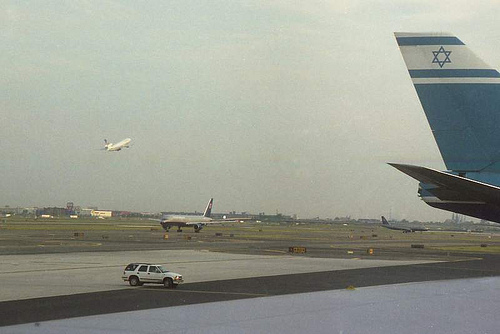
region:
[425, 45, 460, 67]
blue star on a plane's tail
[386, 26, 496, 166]
blue and white plane tail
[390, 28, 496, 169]
tail of an airplane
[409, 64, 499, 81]
blue stripe on a plane wing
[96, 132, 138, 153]
white airplane in the sky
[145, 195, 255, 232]
large grounded airplane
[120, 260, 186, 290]
parked white vehicle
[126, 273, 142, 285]
wheel of a vehicle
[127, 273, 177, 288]
two wheels on a car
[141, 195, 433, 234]
two grounded planes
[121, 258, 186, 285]
a white suv parked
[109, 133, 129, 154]
a white plane flying in the air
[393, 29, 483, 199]
the wing of the airplane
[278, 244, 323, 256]
a box on the ground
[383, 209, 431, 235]
a grey airplane on the ground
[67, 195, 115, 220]
a white building in the background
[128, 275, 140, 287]
the tire of the suv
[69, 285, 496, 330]
the runway of the airport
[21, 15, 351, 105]
a grey sky in the background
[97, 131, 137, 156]
plane taking off at airport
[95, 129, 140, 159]
plane flying out of airport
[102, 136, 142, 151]
plane leaving airport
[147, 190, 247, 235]
plan waiting on the runway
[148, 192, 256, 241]
plane on the runway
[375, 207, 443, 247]
plane sitting on the runway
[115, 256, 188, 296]
car on the tarmac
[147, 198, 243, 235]
plane sitting on the tarmac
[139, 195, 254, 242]
plane waiting to taxi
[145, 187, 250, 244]
grey plane on runway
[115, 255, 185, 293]
white suv on concrete tarmac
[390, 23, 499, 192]
blue and white tail on airplane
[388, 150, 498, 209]
extended wing of airplane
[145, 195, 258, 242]
silver and blue airplane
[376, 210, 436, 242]
dark grey airplane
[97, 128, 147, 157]
white airplane in sky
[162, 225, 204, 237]
wheels on bottom of plane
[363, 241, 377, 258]
white object on tarmac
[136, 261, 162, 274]
windows on side of suv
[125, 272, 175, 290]
two black wheels on side of suv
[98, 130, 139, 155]
The airplane just took off the ground.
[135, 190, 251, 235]
An airplane moving slowly on the runway.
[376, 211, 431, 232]
A grey airplane moving slowly on the runway.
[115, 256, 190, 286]
Car on the airplane's parking lot.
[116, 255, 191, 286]
Car is white.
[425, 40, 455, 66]
Aircraft's tail with a blue logo.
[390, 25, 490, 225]
Tail of a blue and white aircraft.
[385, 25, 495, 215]
The aircraft is at the parking lot.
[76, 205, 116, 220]
Big white house in the background.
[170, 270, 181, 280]
Car's light is turned on.